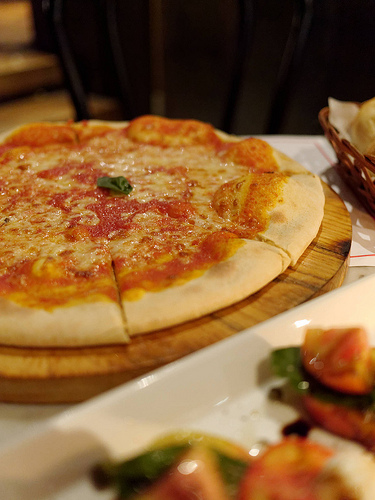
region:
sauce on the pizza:
[97, 204, 136, 235]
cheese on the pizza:
[60, 236, 89, 275]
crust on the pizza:
[73, 309, 111, 340]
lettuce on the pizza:
[93, 171, 132, 201]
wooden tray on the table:
[302, 262, 333, 284]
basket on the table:
[308, 95, 373, 197]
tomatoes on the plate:
[251, 440, 323, 493]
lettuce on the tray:
[109, 450, 166, 484]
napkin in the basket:
[343, 107, 369, 133]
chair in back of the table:
[45, 12, 309, 114]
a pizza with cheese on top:
[8, 110, 331, 347]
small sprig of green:
[95, 170, 133, 194]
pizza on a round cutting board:
[3, 108, 344, 396]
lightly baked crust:
[265, 165, 325, 256]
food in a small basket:
[317, 82, 370, 196]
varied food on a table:
[0, 101, 372, 496]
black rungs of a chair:
[51, 0, 355, 125]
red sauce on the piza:
[78, 195, 139, 230]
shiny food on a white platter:
[278, 324, 373, 446]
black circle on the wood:
[339, 235, 354, 258]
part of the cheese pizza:
[7, 242, 29, 291]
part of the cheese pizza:
[49, 239, 70, 284]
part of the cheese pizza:
[90, 211, 109, 278]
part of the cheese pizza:
[124, 253, 158, 275]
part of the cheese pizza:
[16, 154, 45, 175]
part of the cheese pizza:
[81, 138, 120, 153]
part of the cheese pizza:
[171, 147, 204, 179]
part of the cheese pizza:
[216, 189, 240, 209]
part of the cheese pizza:
[168, 185, 189, 202]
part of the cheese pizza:
[133, 189, 156, 217]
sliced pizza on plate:
[1, 116, 326, 347]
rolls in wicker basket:
[319, 96, 374, 214]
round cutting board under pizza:
[0, 175, 352, 402]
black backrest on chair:
[42, 0, 313, 136]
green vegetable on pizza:
[98, 174, 131, 194]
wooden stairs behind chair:
[0, 48, 120, 121]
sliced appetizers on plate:
[89, 327, 372, 498]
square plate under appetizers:
[1, 270, 372, 497]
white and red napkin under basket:
[230, 134, 372, 265]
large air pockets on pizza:
[4, 118, 282, 290]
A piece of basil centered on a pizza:
[93, 171, 136, 197]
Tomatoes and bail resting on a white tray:
[74, 340, 371, 498]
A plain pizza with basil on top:
[1, 120, 325, 345]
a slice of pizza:
[95, 194, 287, 334]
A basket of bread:
[317, 84, 373, 218]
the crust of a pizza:
[9, 250, 275, 340]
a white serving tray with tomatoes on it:
[0, 273, 373, 499]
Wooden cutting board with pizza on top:
[0, 167, 374, 403]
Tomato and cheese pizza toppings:
[0, 144, 267, 296]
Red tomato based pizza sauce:
[45, 161, 198, 251]